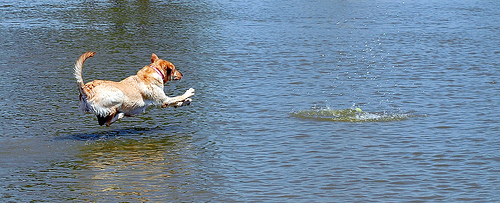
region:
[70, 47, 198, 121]
a wet dog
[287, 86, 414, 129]
a ball is in the water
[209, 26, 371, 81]
blue water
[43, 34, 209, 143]
a dog jumping into the water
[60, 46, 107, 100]
the dog has A tail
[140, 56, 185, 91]
The dog is wearing a collar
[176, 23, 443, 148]
the water isn't smooth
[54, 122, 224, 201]
a reflection of a dog in the water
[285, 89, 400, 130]
the ball is green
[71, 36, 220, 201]
a dog has jumped into the water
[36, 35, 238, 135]
dog jumping over water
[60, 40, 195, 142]
tail curled toward dog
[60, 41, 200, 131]
rear legs bent under body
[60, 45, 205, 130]
front paws stretched out in front to body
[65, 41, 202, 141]
dog close to water surface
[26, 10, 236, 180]
dog surrounded by water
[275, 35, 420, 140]
ball making a splash in water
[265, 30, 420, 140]
curved and wide splash across calm water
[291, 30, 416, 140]
drops of water above broken surface of water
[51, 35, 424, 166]
dog chasing after a ball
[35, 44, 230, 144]
A dog jumping in the water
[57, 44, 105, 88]
The tail of a dog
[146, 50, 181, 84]
The head of a dog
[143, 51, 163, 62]
The left ear of a dog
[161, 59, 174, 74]
The right ear of a dog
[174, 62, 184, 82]
The nose of a dog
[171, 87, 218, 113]
The front paws of a dog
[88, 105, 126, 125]
The back paws of a dog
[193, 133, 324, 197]
Water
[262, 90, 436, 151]
A splash in water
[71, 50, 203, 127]
light brown dog jumping into water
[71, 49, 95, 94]
tail of light brown dog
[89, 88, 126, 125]
hind legs of light brown dog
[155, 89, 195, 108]
front legs of light brown dog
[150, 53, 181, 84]
head of light brown dog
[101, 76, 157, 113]
body of light brown dog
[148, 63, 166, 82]
collar on light brown dog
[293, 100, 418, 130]
splashing water in front of dog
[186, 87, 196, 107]
front paws of dog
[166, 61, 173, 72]
right ear of dog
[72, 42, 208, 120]
dog jumping into water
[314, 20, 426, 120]
water from the splash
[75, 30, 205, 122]
large tan dog in air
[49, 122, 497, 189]
blue calm water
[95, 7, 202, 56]
shadows on the water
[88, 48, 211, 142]
dog wet from water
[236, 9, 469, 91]
during the day time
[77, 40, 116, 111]
dog's tail standing up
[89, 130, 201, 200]
dog's shadow in the water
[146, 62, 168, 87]
collar on the dog